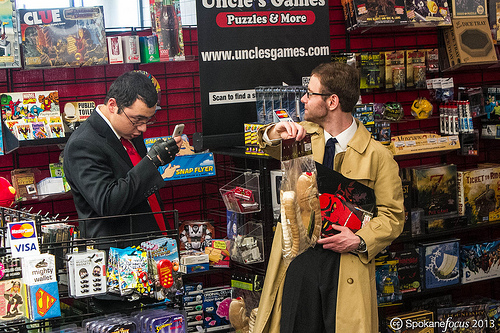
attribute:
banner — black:
[198, 3, 335, 158]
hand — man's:
[260, 118, 298, 143]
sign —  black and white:
[194, 0, 334, 145]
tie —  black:
[319, 136, 339, 193]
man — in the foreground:
[243, 55, 415, 332]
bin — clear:
[216, 171, 266, 214]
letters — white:
[200, 45, 329, 63]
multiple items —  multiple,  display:
[67, 220, 228, 305]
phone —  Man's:
[170, 123, 185, 140]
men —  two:
[50, 59, 192, 278]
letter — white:
[224, 9, 237, 28]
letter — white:
[231, 50, 248, 68]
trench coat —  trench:
[252, 119, 406, 331]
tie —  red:
[120, 135, 165, 234]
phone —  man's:
[171, 114, 184, 150]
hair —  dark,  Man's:
[309, 62, 373, 116]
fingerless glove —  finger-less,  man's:
[129, 128, 180, 163]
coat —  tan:
[245, 118, 405, 331]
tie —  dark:
[312, 132, 335, 193]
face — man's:
[103, 87, 157, 142]